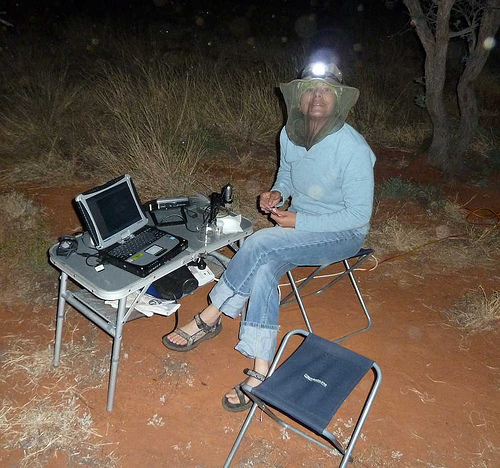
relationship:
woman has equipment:
[160, 47, 386, 418] [49, 170, 239, 296]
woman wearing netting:
[160, 47, 386, 418] [269, 55, 364, 146]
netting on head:
[269, 55, 364, 146] [297, 82, 341, 119]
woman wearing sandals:
[160, 47, 386, 418] [152, 309, 275, 415]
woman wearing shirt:
[160, 47, 386, 418] [250, 120, 384, 242]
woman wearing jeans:
[160, 47, 386, 418] [189, 217, 367, 353]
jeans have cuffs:
[189, 217, 367, 353] [207, 272, 286, 356]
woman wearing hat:
[160, 47, 386, 418] [267, 58, 388, 97]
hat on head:
[267, 58, 388, 97] [297, 82, 341, 119]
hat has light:
[267, 58, 388, 97] [308, 62, 329, 79]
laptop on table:
[69, 174, 182, 276] [45, 189, 254, 409]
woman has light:
[160, 47, 386, 418] [308, 62, 329, 79]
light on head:
[308, 62, 329, 79] [297, 82, 341, 119]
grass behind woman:
[3, 34, 417, 186] [160, 47, 386, 418]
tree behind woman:
[399, 5, 497, 177] [160, 47, 386, 418]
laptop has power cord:
[69, 174, 182, 276] [201, 195, 500, 311]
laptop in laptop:
[69, 174, 182, 276] [70, 171, 192, 278]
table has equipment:
[45, 189, 254, 409] [49, 170, 239, 296]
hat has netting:
[267, 58, 388, 97] [269, 55, 364, 146]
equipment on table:
[49, 170, 239, 296] [45, 189, 254, 409]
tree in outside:
[399, 5, 497, 177] [0, 3, 499, 467]